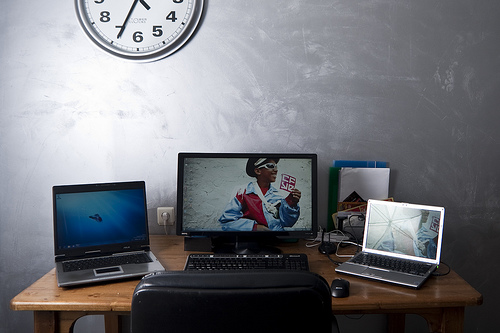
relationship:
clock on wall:
[74, 3, 211, 59] [1, 2, 500, 331]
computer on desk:
[180, 155, 317, 231] [13, 232, 483, 328]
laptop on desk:
[53, 186, 166, 291] [13, 232, 483, 328]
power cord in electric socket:
[162, 221, 172, 233] [156, 206, 176, 225]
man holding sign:
[234, 155, 292, 231] [278, 173, 299, 193]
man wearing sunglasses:
[234, 155, 292, 231] [260, 163, 277, 168]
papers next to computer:
[326, 168, 395, 200] [180, 155, 317, 231]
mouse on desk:
[333, 277, 349, 295] [13, 232, 483, 328]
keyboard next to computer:
[184, 255, 306, 272] [180, 155, 317, 231]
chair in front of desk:
[130, 272, 336, 332] [13, 232, 483, 328]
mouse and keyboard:
[333, 277, 349, 295] [184, 255, 306, 272]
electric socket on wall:
[153, 208, 176, 228] [1, 2, 500, 331]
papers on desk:
[326, 168, 395, 200] [13, 232, 483, 328]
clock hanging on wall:
[74, 3, 211, 59] [1, 2, 500, 331]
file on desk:
[328, 156, 392, 237] [13, 232, 483, 328]